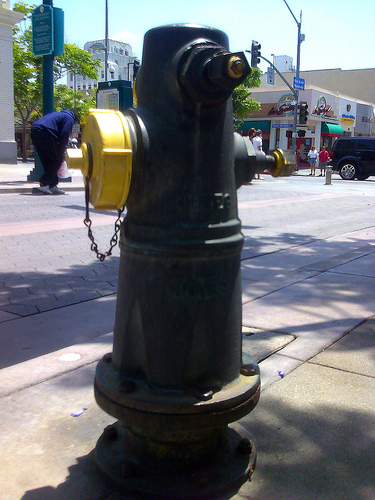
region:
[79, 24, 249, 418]
this is a a hydrant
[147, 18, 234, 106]
this is the top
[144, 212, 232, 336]
the hydrant is metallic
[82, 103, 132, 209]
the stem is yellow in color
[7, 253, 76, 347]
this is the floor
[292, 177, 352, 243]
the road is tarmacked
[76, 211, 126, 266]
this is a chain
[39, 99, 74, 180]
the man is bending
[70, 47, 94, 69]
the tree is leafy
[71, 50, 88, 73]
the leaves are green in color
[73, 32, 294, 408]
a black and yellow fire hydrant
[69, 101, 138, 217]
a yellow fire hydrant cover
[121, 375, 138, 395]
a black bolt on a fire hydrant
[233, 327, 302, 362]
access panel on the sidewalk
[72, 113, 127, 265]
a chain on a metal fire hydrant cap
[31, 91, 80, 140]
a person wearing a blue sweatshirt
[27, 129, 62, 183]
a person wearing black pants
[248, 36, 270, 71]
a traffic light on a horizontal arm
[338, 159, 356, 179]
rear wheel of a vehicle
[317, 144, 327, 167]
a person in a red shirt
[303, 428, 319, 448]
part of a shade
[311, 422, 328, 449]
part of a floor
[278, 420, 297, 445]
part of a shade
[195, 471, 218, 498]
par tof a bolt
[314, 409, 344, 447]
part of a shade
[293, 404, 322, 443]
par tof a shade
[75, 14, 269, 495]
black fire hydrant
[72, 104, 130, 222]
yellow cap on black fire hydrant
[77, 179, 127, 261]
black chain attached to fire hydrant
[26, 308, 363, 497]
shadows on the sidewalk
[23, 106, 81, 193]
man wearing navy sweatshirt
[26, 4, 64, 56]
green and white street sign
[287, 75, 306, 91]
blue and white street sign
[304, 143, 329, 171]
people standing on sidewalk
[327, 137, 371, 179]
black suv driving on the street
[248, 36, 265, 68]
black traffic signal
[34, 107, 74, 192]
Person wearing blue shirt and black pants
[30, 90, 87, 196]
Person wearing blue shirt and black pants bending over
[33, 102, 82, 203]
Person wearing white shoes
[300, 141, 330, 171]
Two people across the street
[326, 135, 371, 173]
Blue automobile on the street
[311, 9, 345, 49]
Clear blue sky with no clouds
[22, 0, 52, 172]
Blue sign on sidewalk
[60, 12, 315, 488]
Fire hydrant on sidewalk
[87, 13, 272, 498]
Fire hydrant on sidewalk with yellow attachment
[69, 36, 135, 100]
Tall white building